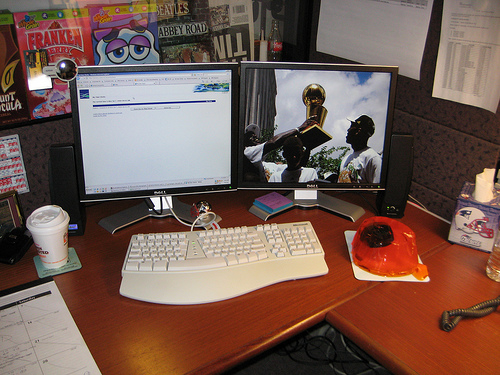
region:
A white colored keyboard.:
[119, 220, 329, 307]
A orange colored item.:
[348, 213, 427, 280]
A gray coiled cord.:
[439, 293, 499, 335]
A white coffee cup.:
[23, 200, 70, 270]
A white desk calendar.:
[0, 275, 102, 374]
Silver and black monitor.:
[232, 60, 399, 222]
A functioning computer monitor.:
[68, 60, 239, 237]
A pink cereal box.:
[14, 5, 95, 120]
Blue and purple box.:
[91, 3, 161, 75]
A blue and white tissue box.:
[443, 168, 498, 250]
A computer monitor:
[65, 60, 242, 232]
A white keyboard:
[119, 218, 331, 305]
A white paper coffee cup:
[24, 203, 70, 268]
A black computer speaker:
[375, 130, 415, 217]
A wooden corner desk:
[0, 188, 496, 374]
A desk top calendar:
[0, 277, 102, 374]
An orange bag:
[351, 214, 427, 281]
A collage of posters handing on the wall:
[0, 0, 261, 128]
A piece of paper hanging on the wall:
[430, 0, 499, 112]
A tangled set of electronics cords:
[276, 321, 386, 374]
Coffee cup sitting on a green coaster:
[24, 204, 82, 279]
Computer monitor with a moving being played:
[238, 61, 401, 187]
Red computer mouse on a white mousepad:
[342, 216, 427, 281]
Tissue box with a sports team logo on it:
[447, 167, 499, 253]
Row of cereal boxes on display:
[0, 3, 182, 129]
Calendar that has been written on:
[0, 275, 98, 374]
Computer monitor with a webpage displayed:
[73, 62, 240, 204]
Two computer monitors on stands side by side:
[65, 61, 400, 236]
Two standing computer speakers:
[42, 133, 434, 235]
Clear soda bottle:
[265, 18, 283, 63]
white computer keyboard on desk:
[116, 219, 329, 301]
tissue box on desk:
[447, 180, 499, 255]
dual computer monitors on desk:
[67, 62, 400, 234]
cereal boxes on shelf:
[11, 0, 162, 114]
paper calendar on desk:
[2, 277, 104, 374]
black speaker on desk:
[377, 134, 411, 220]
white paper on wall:
[431, 2, 498, 114]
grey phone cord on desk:
[437, 296, 499, 335]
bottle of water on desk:
[486, 229, 499, 283]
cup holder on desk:
[33, 246, 83, 281]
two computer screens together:
[64, 55, 402, 216]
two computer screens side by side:
[62, 63, 400, 213]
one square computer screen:
[240, 62, 392, 194]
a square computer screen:
[71, 59, 239, 207]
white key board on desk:
[120, 221, 325, 308]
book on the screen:
[300, 119, 331, 151]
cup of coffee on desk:
[21, 199, 81, 280]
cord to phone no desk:
[448, 292, 492, 333]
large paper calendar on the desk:
[2, 279, 97, 373]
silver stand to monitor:
[322, 192, 366, 226]